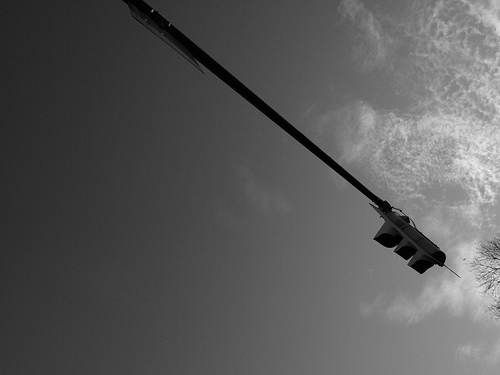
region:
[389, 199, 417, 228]
Wire on traffic signal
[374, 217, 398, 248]
first light bulb on traffic signal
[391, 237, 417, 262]
middle light on traffic signal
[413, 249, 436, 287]
lower light on traffic signal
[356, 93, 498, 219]
clouds in the sky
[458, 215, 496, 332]
Tree at edge of picture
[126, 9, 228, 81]
street sign attached to arm of traffic signal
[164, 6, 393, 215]
arm holding traffic signal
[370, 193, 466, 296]
traffic signal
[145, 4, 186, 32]
brackets holding street sign on arm of signal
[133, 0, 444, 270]
a traffic light and pole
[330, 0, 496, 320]
white clouds in the sky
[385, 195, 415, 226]
the electrical wires on the back of the pole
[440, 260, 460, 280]
data link antenna to a master traffic signal controller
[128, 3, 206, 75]
a sign attached to the traffic signal pole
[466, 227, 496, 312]
a tree without any leaves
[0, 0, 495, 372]
a black and white photo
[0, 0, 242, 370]
clear skies on half of the picture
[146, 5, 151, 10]
the mounting bolts and nuts for the sign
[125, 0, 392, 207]
the traffic light pole is black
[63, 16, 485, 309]
This is a photo of a stoplight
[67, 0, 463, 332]
The photo is in black and white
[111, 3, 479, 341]
There is a sign attached to the stop light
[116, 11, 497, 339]
There are clouds in the sky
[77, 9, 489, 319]
The photo was taken looking up at the stoplight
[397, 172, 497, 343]
There are branches in the right side of the photo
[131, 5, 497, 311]
The stoplight is next to the branches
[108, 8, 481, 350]
There is only one stoplight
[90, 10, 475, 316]
There is only one sign attached to the stoplight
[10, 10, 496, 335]
The clouds are localized to the right of the photo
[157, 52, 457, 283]
traffic light at an angle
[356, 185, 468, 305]
three protrusions on end of pole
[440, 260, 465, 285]
wire sticking out at end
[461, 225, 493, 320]
top of tree with bare branches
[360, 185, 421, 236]
wire in back of lights connecting to pole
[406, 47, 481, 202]
clouds against grey sky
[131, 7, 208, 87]
edge of sign on pole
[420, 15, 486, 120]
lacy pattern of clouds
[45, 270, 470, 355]
sky lightening up toward clouds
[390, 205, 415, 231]
bump on back of traffic lights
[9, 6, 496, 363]
outdoor cloudy daytime scene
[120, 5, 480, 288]
traffic light against sky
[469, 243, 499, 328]
tree without leaves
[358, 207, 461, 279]
three traffic lights surrounded by metal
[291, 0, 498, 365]
white cloud formations in sky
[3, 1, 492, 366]
this is a black and white photograph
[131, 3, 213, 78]
sign affixr=ed to metal pole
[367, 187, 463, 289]
electrical wires around lights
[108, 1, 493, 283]
traffic light pole silhouetted against sky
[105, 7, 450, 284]
three round traffic lights mounted on pole